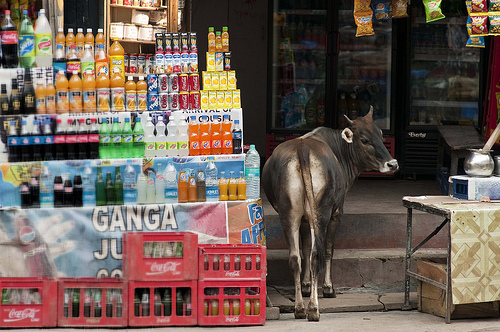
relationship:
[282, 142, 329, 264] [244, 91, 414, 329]
tail of a cow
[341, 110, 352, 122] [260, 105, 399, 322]
horn on cow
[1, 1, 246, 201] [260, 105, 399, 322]
soda on cow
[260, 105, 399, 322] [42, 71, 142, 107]
cow on soda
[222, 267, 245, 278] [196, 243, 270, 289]
logo on bin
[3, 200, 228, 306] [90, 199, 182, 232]
sign on lettering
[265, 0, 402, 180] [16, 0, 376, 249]
refrigerator on building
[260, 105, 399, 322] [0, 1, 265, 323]
cow on drinks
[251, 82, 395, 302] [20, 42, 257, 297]
cow standing next to drinks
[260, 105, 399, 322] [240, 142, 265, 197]
cow standing next to drink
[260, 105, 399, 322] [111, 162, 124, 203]
cow standing next to drink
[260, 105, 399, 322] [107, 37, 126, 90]
cow standing next to drink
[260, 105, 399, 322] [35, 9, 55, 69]
cow standing next to drink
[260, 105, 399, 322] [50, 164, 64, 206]
cow standing next to drink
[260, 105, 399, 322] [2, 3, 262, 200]
cow standing next to drinks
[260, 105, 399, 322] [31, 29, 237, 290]
cow standing next to drinks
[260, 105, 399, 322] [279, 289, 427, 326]
cow standing on sidewalk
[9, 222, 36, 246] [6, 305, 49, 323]
logo on sign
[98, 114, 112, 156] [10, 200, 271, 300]
soda on table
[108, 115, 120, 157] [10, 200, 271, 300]
soda on table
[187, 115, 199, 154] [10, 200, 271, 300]
soda on table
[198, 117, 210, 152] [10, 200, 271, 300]
soda on table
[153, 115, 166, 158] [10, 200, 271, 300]
soda on table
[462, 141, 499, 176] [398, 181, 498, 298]
pot on table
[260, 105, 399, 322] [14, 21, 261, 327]
cow next to drinks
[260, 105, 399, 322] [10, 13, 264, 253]
cow standing next to drinks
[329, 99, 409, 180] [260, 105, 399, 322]
head of a cow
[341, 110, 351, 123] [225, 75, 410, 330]
ear of a cow